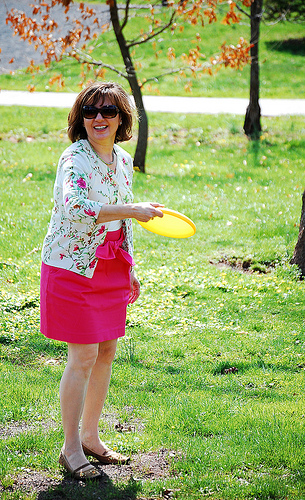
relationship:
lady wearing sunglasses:
[33, 74, 195, 485] [79, 105, 120, 120]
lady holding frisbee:
[33, 74, 195, 485] [143, 197, 213, 270]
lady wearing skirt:
[33, 74, 195, 485] [41, 256, 136, 349]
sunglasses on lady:
[79, 105, 120, 120] [33, 74, 195, 485]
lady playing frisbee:
[33, 74, 195, 485] [143, 197, 213, 270]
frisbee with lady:
[143, 197, 213, 270] [33, 74, 195, 485]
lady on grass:
[33, 74, 195, 485] [184, 268, 269, 346]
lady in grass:
[33, 74, 195, 485] [184, 268, 269, 346]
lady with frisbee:
[33, 74, 195, 485] [143, 197, 213, 270]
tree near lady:
[99, 18, 187, 78] [33, 74, 195, 485]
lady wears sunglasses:
[33, 74, 195, 485] [79, 105, 120, 120]